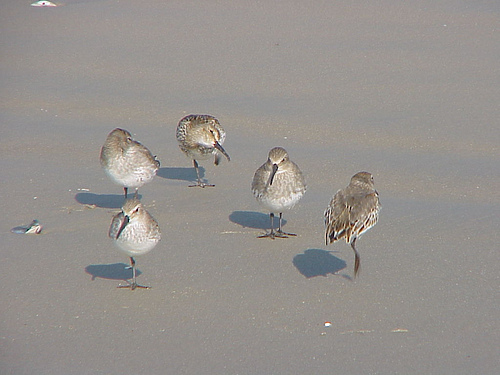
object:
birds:
[109, 194, 164, 291]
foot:
[188, 181, 216, 189]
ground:
[0, 0, 498, 375]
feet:
[256, 232, 290, 240]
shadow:
[229, 210, 287, 233]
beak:
[270, 163, 279, 185]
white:
[324, 321, 331, 327]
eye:
[136, 207, 139, 213]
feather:
[10, 219, 44, 234]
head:
[186, 119, 221, 148]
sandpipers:
[99, 127, 160, 199]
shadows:
[155, 166, 208, 185]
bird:
[251, 146, 308, 240]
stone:
[320, 331, 327, 335]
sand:
[0, 0, 500, 141]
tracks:
[83, 202, 95, 210]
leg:
[193, 159, 203, 184]